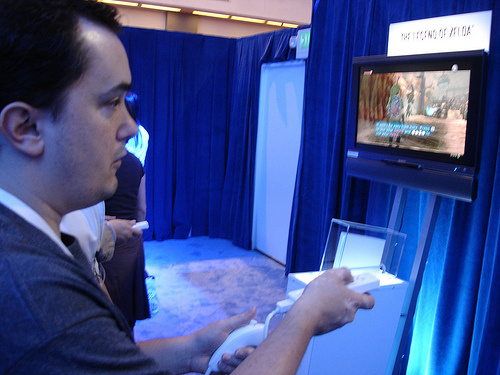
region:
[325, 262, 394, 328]
Man is holding a Wii remote.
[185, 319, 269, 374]
Man is holding nunchucks.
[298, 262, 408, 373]
The gaming system is white.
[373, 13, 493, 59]
Sign above the screen.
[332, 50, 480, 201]
The TV is blue.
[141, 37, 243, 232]
The curtain is blue.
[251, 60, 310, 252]
The door is white.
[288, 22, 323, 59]
Exit sign above the door.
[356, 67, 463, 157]
Video game on the screen.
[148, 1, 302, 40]
Lights on the ceiling.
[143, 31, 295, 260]
blue drapes around the room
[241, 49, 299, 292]
door is white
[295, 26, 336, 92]
exit sign above the door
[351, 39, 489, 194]
television in front of drapes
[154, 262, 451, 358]
man holding two wii remotes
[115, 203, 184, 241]
another person holding a wii remote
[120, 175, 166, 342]
woman has her back to the wii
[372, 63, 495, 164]
television is on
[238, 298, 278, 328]
man has his thumb on the button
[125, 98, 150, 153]
woman has long hair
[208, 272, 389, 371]
White WII controller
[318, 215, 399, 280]
White WII console in clear case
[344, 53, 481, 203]
black flat screen television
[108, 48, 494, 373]
Long blue colored curtains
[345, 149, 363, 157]
White symbol on television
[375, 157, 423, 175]
Black control buttons on telivision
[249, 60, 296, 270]
White rectangular door frame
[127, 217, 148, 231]
White colored WII controler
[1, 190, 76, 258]
White lanyard around man's neck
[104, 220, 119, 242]
Light colored wrist braclet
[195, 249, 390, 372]
Two hands holding wiimote and nunchuck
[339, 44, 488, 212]
Flat screen displaying Hyrule Warriors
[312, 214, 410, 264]
Wii game console inside display case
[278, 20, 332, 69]
Green exit sign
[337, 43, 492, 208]
Link from Zelda standing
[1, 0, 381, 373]
Man playing wii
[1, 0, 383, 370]
Guy in black t-shirt playing a video game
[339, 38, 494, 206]
Wii sensor bar attached to black flat television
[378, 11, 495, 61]
White sign reading "The Legend of Zelda"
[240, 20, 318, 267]
White exit door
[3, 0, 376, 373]
a man with thinning hair.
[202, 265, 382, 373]
a wii game controller.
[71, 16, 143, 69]
a receeding hair line.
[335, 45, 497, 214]
a TV with a game on it.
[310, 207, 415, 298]
a cube with a gaming system.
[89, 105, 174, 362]
a woman standing.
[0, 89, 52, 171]
a right human ear.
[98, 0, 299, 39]
lights on a wall.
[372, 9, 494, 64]
a sign above a TV monitor.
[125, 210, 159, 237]
a gaming controller.